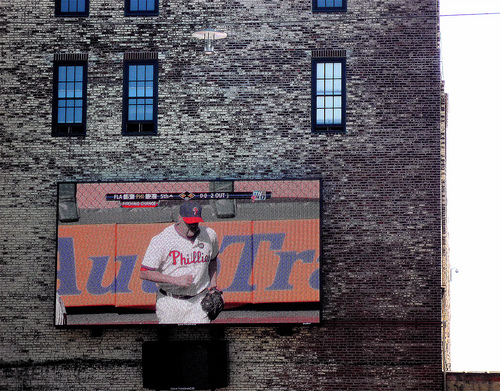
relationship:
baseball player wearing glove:
[138, 201, 224, 324] [201, 292, 226, 316]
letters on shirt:
[168, 249, 210, 265] [151, 241, 216, 300]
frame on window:
[53, 54, 87, 134] [54, 54, 87, 137]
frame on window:
[121, 54, 160, 134] [122, 52, 156, 133]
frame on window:
[312, 52, 345, 133] [309, 48, 346, 130]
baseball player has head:
[138, 201, 224, 324] [172, 198, 207, 241]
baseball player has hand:
[138, 201, 224, 324] [153, 262, 197, 298]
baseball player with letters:
[138, 201, 224, 324] [178, 251, 195, 268]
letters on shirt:
[178, 251, 195, 268] [140, 224, 225, 294]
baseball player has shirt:
[138, 201, 224, 324] [140, 224, 225, 294]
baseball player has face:
[138, 201, 224, 324] [182, 222, 198, 237]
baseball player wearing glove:
[138, 201, 224, 324] [201, 287, 223, 320]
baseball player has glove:
[138, 201, 224, 324] [199, 287, 226, 320]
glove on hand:
[199, 287, 226, 320] [198, 286, 225, 296]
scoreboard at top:
[93, 186, 283, 206] [82, 184, 314, 215]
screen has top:
[55, 178, 322, 329] [82, 184, 314, 215]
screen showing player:
[48, 178, 328, 333] [143, 201, 237, 330]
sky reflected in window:
[18, 11, 418, 73] [117, 50, 164, 135]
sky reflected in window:
[18, 11, 418, 73] [50, 52, 90, 135]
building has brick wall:
[1, 1, 493, 389] [348, 2, 440, 389]